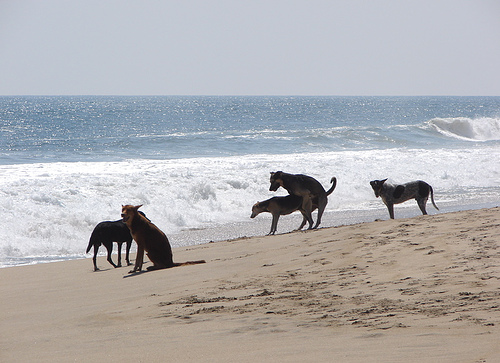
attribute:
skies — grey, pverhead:
[92, 24, 432, 99]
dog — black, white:
[366, 173, 439, 223]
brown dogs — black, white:
[85, 169, 440, 273]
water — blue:
[8, 87, 498, 268]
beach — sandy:
[0, 201, 498, 361]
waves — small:
[141, 112, 498, 146]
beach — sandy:
[0, 188, 479, 361]